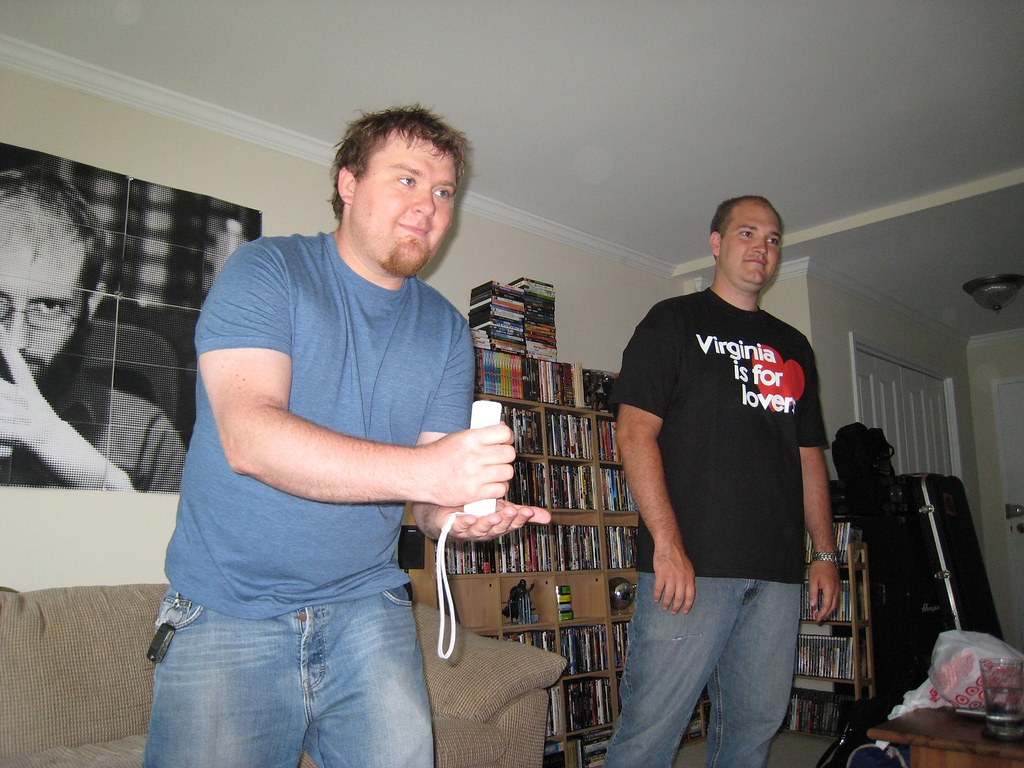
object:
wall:
[0, 68, 685, 594]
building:
[0, 0, 1024, 768]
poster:
[0, 141, 263, 495]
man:
[140, 102, 548, 767]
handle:
[436, 510, 461, 660]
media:
[545, 408, 592, 460]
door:
[851, 340, 972, 483]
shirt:
[164, 232, 831, 620]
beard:
[377, 235, 432, 278]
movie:
[552, 525, 600, 573]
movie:
[597, 421, 621, 463]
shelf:
[595, 412, 622, 466]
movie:
[571, 363, 585, 408]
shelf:
[544, 403, 601, 462]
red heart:
[752, 345, 805, 413]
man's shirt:
[605, 283, 828, 584]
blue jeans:
[140, 587, 436, 767]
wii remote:
[463, 399, 503, 518]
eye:
[398, 178, 414, 187]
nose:
[411, 186, 435, 219]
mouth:
[397, 220, 432, 236]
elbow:
[226, 450, 252, 474]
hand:
[414, 424, 516, 509]